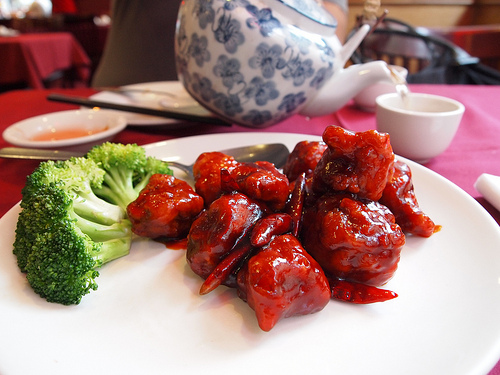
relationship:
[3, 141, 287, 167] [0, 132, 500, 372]
silver spoon lying on white plate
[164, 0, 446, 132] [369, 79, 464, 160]
teapot pouring tea teacup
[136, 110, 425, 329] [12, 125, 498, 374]
food on a plate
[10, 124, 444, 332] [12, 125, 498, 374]
food on a plate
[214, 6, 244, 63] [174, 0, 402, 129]
flower on kettle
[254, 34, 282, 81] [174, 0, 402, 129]
flower on kettle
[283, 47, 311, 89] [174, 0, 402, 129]
flower on kettle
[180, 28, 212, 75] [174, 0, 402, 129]
flower on kettle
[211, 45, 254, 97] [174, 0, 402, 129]
flower on kettle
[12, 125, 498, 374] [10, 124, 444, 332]
plate with food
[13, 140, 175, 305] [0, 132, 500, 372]
broccoli on a white plate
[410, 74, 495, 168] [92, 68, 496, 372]
tablecloth on table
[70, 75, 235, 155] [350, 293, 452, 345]
chopsticks on plate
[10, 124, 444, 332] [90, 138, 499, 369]
food on plate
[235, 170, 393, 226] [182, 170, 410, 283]
meat covered in sauce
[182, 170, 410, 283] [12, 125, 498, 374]
sauce on plate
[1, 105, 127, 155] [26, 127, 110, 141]
dish with sauce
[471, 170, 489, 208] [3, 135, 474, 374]
napkin by plate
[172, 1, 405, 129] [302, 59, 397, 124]
teapot has spout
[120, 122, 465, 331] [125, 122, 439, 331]
wings covered with sauce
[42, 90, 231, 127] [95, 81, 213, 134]
chpsticks on edge of plate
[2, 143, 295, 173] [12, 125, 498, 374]
spoon laying on plate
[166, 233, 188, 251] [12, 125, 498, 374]
sauce smeared on plate